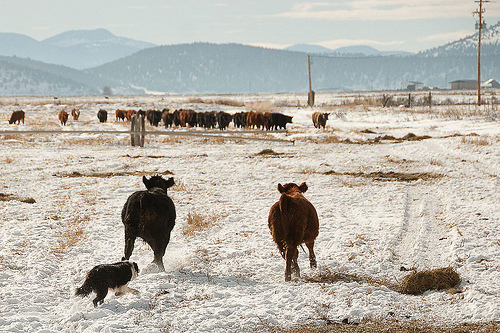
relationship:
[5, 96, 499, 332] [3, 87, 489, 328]
snow on pasture